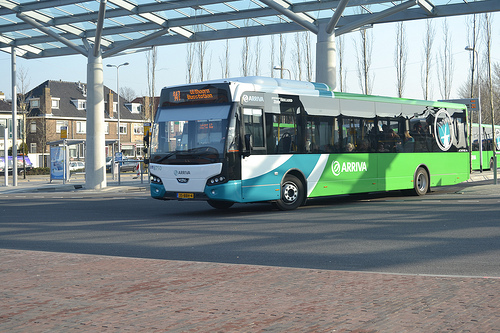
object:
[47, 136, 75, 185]
bus stop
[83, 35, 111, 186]
structure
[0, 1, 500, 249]
shelter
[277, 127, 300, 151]
people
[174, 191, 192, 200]
license plate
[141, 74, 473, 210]
metro bus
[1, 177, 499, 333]
street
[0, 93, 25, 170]
building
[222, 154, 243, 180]
black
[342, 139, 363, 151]
people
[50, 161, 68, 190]
shelter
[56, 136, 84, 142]
roof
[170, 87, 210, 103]
digital letters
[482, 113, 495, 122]
leaves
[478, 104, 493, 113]
canopy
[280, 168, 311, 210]
wheel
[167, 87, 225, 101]
sign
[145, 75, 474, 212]
bus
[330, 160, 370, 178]
logo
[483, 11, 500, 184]
tree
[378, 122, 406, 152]
people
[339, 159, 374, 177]
arriba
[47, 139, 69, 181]
billboard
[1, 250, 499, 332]
sidewalk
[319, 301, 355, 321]
bricks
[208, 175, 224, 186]
lights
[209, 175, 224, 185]
headlights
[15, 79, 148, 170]
house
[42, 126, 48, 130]
brick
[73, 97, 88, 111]
windows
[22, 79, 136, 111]
roof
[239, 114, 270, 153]
drivers window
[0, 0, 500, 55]
roof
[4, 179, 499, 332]
road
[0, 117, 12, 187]
white post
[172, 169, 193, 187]
writing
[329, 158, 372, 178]
company name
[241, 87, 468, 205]
side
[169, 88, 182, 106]
bus number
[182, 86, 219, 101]
route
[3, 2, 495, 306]
bus terminal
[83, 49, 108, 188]
cement pillars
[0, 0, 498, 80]
covering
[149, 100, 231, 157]
window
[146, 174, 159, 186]
headlights